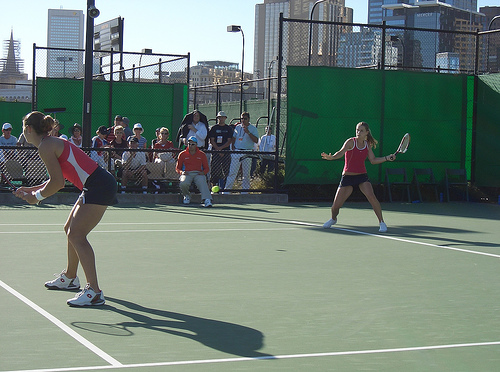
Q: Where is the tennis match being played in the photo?
A: Tennis court.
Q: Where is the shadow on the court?
A: Woman in white and red tennis.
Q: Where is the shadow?
A: On the court.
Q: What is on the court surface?
A: A shadow.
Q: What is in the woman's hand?
A: A racquet.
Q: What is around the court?
A: A fence.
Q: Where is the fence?
A: Around the court.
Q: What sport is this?
A: Tennis.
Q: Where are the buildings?
A: Behind the court.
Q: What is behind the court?
A: Buildings.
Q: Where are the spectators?
A: Outside the fence.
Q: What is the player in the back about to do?
A: Hit the ball.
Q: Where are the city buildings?
A: In the horizon.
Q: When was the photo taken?
A: Daylight.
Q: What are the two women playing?
A: Tennis.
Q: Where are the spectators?
A: Behind the fence.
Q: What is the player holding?
A: Racket.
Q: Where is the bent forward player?
A: On court.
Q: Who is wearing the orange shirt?
A: Play watcher.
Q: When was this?
A: Daytime.